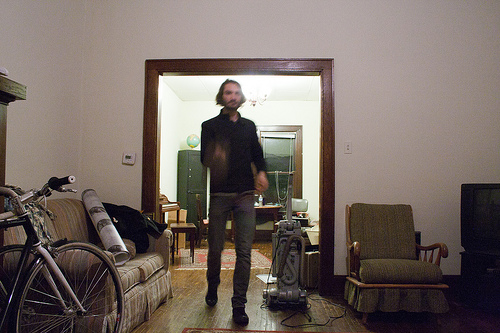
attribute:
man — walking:
[200, 78, 270, 325]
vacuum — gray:
[263, 185, 309, 310]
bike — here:
[0, 174, 127, 333]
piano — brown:
[160, 193, 181, 228]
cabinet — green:
[179, 149, 208, 221]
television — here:
[460, 182, 500, 252]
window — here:
[258, 130, 294, 204]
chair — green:
[347, 204, 451, 315]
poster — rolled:
[80, 188, 132, 265]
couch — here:
[2, 198, 171, 332]